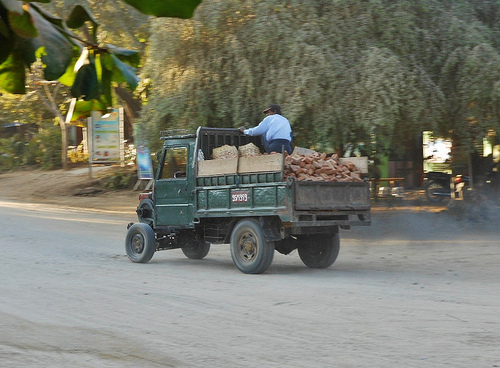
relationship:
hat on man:
[264, 104, 280, 113] [241, 105, 294, 155]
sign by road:
[85, 115, 125, 163] [2, 208, 499, 367]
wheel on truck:
[228, 218, 274, 274] [122, 121, 376, 273]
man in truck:
[241, 105, 294, 155] [122, 121, 376, 273]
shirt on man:
[243, 111, 293, 142] [241, 105, 294, 155]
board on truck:
[193, 152, 284, 174] [122, 121, 376, 273]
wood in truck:
[304, 165, 314, 176] [122, 121, 376, 273]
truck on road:
[122, 121, 376, 273] [2, 208, 499, 367]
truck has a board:
[122, 121, 376, 273] [193, 152, 284, 174]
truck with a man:
[122, 121, 376, 273] [241, 105, 294, 155]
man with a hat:
[241, 105, 294, 155] [264, 104, 280, 113]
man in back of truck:
[241, 105, 294, 155] [122, 121, 376, 273]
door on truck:
[150, 143, 193, 228] [122, 121, 376, 273]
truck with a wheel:
[122, 121, 376, 273] [228, 218, 274, 274]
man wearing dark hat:
[241, 105, 294, 155] [264, 104, 280, 113]